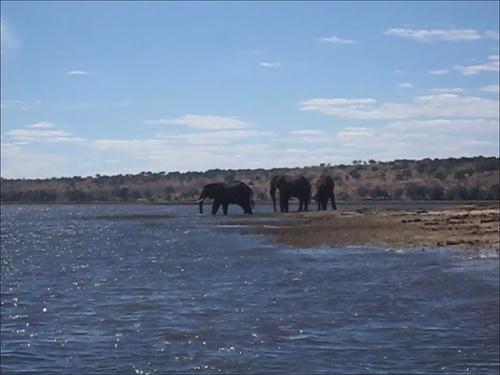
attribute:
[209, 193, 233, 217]
leg — gray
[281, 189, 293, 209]
grey leg — grey 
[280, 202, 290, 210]
grey leg — grey 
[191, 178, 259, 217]
elephant — large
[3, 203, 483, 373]
water — clear, large, rippled, blue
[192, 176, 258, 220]
elephant — tall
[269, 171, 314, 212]
elephant — tall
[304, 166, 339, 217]
elephant — tall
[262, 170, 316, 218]
elephant — large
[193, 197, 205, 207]
tusk — white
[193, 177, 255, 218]
elephant — large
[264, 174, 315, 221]
elephant — large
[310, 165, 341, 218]
elephant — large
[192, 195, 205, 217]
trunk — large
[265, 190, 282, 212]
trunk — large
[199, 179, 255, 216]
elephant — large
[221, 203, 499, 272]
sand bar — brown, damp, sandy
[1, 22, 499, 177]
clouds — thin, wispy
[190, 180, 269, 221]
elephant — large , grey  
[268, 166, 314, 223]
elephant — grey  , large 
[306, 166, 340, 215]
elephant — grey  , large 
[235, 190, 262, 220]
leg — grey 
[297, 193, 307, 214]
leg —  grey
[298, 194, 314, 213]
leg —  grey